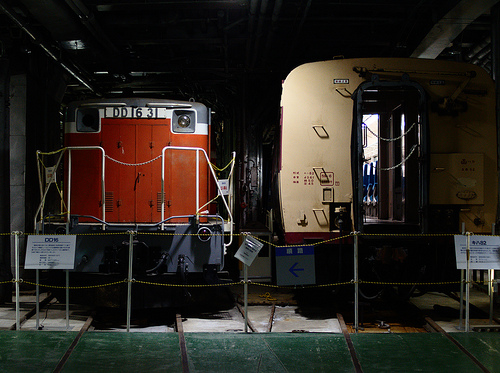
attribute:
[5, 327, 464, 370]
floor — green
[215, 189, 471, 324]
rail — small, metal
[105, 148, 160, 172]
chain — metal, grey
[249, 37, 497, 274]
train — beige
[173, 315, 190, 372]
rail — small, metal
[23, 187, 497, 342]
rail — small, old, metal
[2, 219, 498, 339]
fencing — thin, gray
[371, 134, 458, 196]
chain — blocking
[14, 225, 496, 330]
rail — metal, small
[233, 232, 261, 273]
paper — hanging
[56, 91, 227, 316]
train — red, grey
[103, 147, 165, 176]
chain — suspended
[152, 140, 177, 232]
post — metal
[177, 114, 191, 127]
headlight — round, dark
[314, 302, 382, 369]
metal rail — old, small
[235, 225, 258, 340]
rail — metal, small, old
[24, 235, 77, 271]
shaped sign — rectangular, blue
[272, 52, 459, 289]
train — partially shaded, tan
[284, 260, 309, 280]
arrow — blue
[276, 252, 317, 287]
blue arrow — one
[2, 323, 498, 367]
floor — green